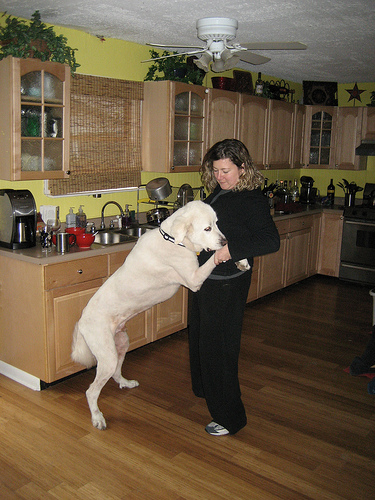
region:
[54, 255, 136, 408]
dog standing on its hind legs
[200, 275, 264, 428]
woman wearing black pants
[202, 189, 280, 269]
woman wearing black shirt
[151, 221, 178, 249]
dog wearing a collar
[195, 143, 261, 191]
woman with blonde and brown hair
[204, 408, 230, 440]
woman wearing white and gray sneakers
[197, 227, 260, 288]
woman holding a dogs paws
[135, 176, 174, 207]
pots in a dish strainer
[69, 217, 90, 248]
red bowls on a counter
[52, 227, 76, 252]
coffee mug on the counter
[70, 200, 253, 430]
a white colored large dog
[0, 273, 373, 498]
a brown colored hardwood floor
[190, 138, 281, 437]
a woman wearing black pants and shirt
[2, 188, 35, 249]
a silver and black coffee pot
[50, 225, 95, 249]
three round red bowls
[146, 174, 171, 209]
a silver pot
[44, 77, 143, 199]
a covered window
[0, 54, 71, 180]
a cabinet with glass in the door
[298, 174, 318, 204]
a black and silver mixer with a silver bowl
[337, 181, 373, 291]
a silver stove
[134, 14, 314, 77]
White ceiling fan hanging on the ceiling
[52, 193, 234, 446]
Dog standing on its hind legs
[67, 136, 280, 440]
Woman dancing with a dog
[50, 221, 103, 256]
Red bowls sitting on a counter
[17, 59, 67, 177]
Glass panes in a cabinet door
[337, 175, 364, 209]
Bucket of utensils sitting on the counter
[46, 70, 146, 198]
Bamboo shade covering a window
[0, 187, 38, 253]
Coffee maker sitting on the edge of the counter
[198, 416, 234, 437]
Front of a grey and white sneaker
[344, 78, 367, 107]
Star sitting on top of a cabinet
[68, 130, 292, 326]
WOMAN WITH A DOG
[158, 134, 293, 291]
WOMAN IS HOLDING DOGS PAW WITH HER LEFT HAND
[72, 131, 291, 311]
WOMAN AND DOG APPEAR TO BE DANCING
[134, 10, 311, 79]
CEILING FAN ON CEILING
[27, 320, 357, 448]
DOG AND PERSON STANDING ON HARDWOOD FLOOR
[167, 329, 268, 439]
PERSON WEARING TENNIS SHOES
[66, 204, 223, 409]
THE DOG IS WHITE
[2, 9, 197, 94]
PLANTS ON TOP OF CABINETS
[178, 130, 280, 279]
WOMAN IS WEARING BLACK JACKET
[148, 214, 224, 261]
COLLAR AROUNG DOGS NECK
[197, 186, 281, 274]
black cotton sweat shirt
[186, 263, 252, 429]
black cotton sweat pants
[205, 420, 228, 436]
grey and white sneakers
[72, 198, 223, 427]
white dog in kitchen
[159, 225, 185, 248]
black and white collar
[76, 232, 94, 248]
red bowl on counter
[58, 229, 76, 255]
coffee mug on counter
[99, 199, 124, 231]
grey metal sink faucet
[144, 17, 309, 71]
white fan on ceiling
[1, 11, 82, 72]
green plant on cabinet